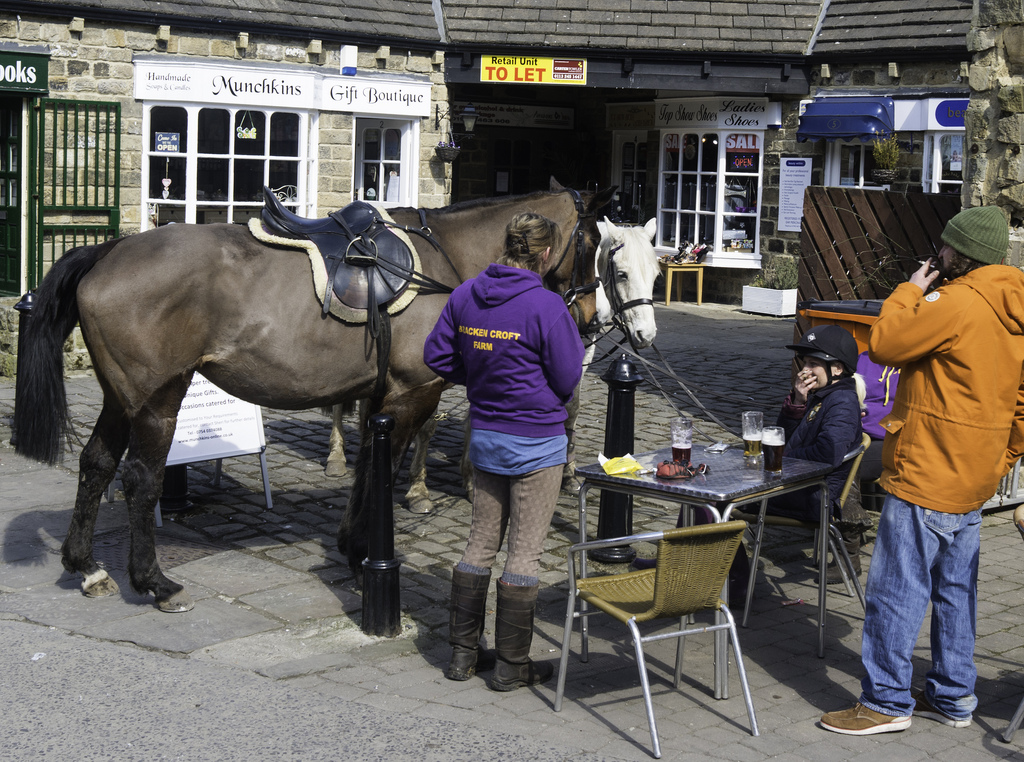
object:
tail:
[15, 235, 131, 468]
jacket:
[868, 264, 1023, 514]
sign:
[480, 54, 587, 85]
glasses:
[670, 411, 764, 463]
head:
[597, 216, 664, 349]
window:
[141, 100, 320, 233]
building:
[0, 2, 451, 379]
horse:
[14, 175, 621, 612]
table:
[574, 443, 833, 700]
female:
[423, 205, 586, 691]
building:
[0, 0, 1023, 387]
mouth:
[803, 377, 818, 386]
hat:
[785, 325, 859, 371]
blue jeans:
[858, 491, 983, 721]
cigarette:
[918, 260, 936, 268]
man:
[820, 205, 1024, 736]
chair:
[555, 520, 760, 760]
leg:
[721, 604, 761, 737]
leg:
[628, 619, 663, 759]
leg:
[554, 553, 576, 712]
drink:
[761, 426, 785, 473]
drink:
[671, 418, 693, 462]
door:
[0, 90, 37, 298]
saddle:
[248, 185, 423, 323]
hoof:
[159, 588, 196, 612]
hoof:
[81, 569, 120, 598]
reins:
[580, 323, 783, 444]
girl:
[632, 324, 867, 605]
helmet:
[785, 324, 859, 387]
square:
[0, 301, 1024, 762]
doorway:
[38, 96, 121, 286]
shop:
[441, 0, 1024, 307]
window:
[653, 129, 764, 269]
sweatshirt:
[424, 262, 585, 438]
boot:
[448, 564, 496, 680]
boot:
[491, 577, 554, 692]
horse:
[320, 215, 664, 514]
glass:
[385, 129, 401, 161]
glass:
[364, 162, 380, 200]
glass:
[269, 160, 298, 202]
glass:
[234, 159, 265, 203]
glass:
[197, 157, 229, 202]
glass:
[149, 156, 187, 201]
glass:
[198, 108, 230, 154]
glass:
[235, 110, 266, 155]